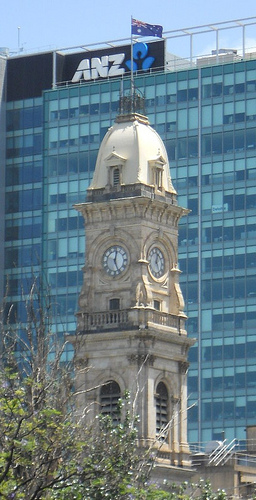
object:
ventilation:
[111, 166, 120, 189]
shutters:
[155, 381, 172, 443]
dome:
[87, 112, 180, 196]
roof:
[38, 50, 255, 118]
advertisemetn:
[70, 42, 165, 83]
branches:
[10, 279, 130, 490]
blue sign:
[124, 42, 154, 72]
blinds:
[97, 375, 126, 439]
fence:
[191, 438, 256, 465]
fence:
[221, 481, 255, 498]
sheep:
[97, 240, 130, 278]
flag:
[130, 17, 163, 41]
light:
[144, 370, 160, 446]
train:
[124, 14, 134, 118]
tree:
[0, 271, 149, 498]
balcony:
[79, 305, 184, 336]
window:
[200, 307, 210, 330]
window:
[212, 276, 223, 308]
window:
[221, 305, 235, 336]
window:
[222, 100, 236, 130]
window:
[221, 128, 233, 158]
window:
[187, 134, 199, 162]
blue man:
[125, 36, 154, 72]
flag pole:
[15, 24, 22, 49]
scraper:
[2, 1, 256, 448]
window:
[202, 77, 211, 101]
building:
[0, 13, 256, 497]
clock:
[147, 246, 164, 282]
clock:
[98, 242, 130, 279]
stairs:
[198, 436, 239, 468]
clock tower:
[64, 77, 197, 469]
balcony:
[191, 438, 254, 465]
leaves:
[3, 368, 84, 498]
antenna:
[118, 75, 124, 106]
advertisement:
[209, 203, 227, 213]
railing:
[73, 306, 187, 331]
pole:
[130, 14, 135, 98]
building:
[64, 85, 196, 486]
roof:
[115, 94, 149, 124]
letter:
[70, 56, 91, 82]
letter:
[91, 53, 111, 79]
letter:
[107, 50, 126, 76]